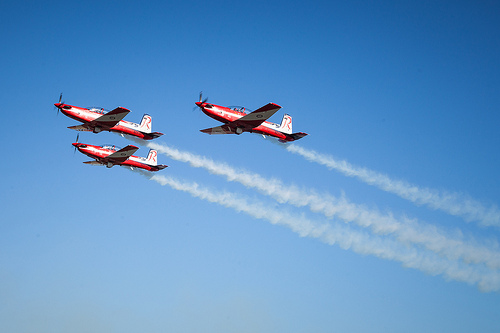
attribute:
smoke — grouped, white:
[176, 132, 489, 302]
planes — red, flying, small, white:
[46, 80, 308, 203]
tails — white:
[138, 96, 305, 182]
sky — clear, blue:
[0, 3, 498, 331]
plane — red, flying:
[192, 86, 306, 150]